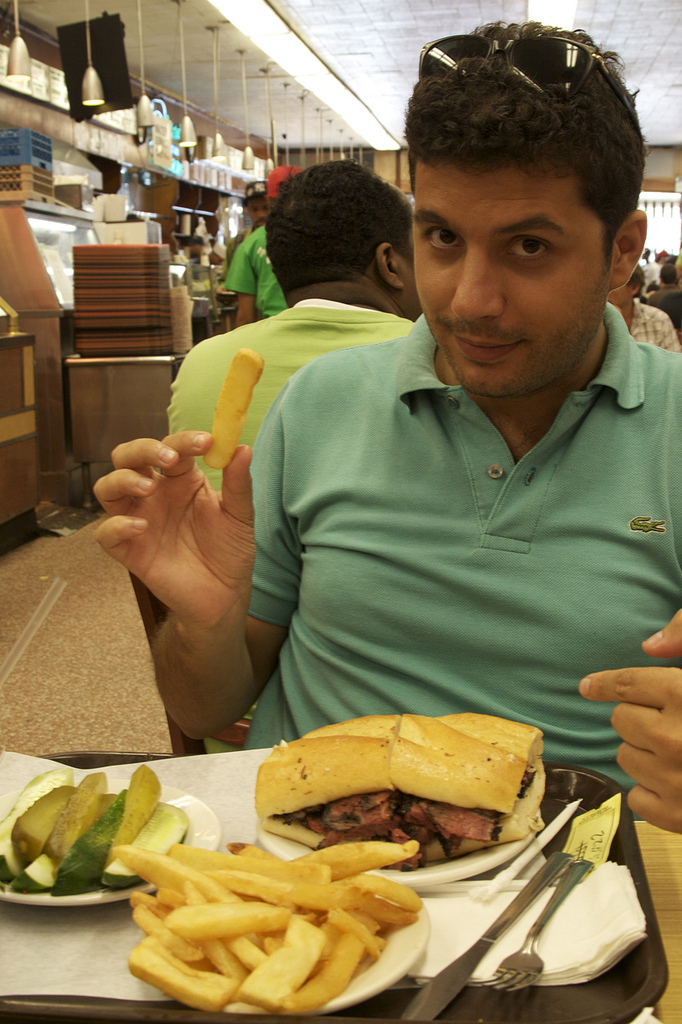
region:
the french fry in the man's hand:
[205, 345, 265, 481]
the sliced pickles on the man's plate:
[6, 763, 179, 892]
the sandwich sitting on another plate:
[257, 716, 540, 862]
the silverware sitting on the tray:
[403, 842, 589, 1023]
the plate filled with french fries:
[106, 833, 432, 1010]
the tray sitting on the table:
[8, 751, 657, 1022]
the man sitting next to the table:
[95, 21, 674, 779]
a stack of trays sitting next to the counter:
[66, 241, 171, 357]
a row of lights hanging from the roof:
[1, 2, 316, 181]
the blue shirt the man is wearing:
[232, 302, 681, 753]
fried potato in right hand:
[85, 338, 269, 632]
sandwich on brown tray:
[249, 703, 644, 897]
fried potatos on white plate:
[111, 817, 432, 1010]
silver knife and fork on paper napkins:
[399, 845, 592, 1017]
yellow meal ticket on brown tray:
[553, 779, 632, 889]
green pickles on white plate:
[5, 761, 221, 910]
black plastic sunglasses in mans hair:
[401, 12, 649, 414]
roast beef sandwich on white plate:
[239, 710, 552, 885]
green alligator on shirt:
[617, 511, 673, 541]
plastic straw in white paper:
[458, 788, 591, 910]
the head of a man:
[391, 81, 613, 398]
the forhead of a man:
[454, 165, 528, 235]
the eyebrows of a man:
[500, 200, 564, 238]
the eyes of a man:
[411, 225, 568, 269]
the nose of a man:
[444, 256, 514, 324]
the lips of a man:
[444, 330, 527, 367]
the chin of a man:
[465, 359, 513, 411]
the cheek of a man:
[518, 287, 566, 333]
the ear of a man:
[594, 217, 662, 298]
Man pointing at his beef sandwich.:
[94, 21, 680, 834]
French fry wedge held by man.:
[205, 348, 264, 469]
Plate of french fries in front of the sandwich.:
[110, 838, 418, 1013]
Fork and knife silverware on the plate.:
[401, 852, 591, 1019]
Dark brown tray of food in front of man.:
[0, 716, 670, 1022]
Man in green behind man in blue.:
[166, 159, 422, 495]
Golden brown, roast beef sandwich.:
[256, 711, 545, 869]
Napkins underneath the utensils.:
[409, 860, 647, 987]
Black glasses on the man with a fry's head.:
[418, 37, 640, 125]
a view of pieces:
[45, 806, 191, 893]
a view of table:
[9, 928, 137, 1005]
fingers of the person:
[598, 608, 661, 817]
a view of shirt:
[308, 465, 639, 826]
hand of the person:
[38, 418, 277, 663]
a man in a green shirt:
[252, 33, 680, 789]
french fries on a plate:
[123, 850, 409, 981]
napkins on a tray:
[373, 884, 656, 959]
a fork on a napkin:
[490, 880, 600, 986]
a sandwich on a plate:
[260, 719, 529, 847]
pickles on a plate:
[6, 780, 191, 875]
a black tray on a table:
[18, 754, 662, 1017]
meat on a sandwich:
[328, 787, 478, 829]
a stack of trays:
[75, 243, 167, 352]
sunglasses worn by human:
[407, 29, 642, 146]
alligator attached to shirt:
[623, 506, 671, 542]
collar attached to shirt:
[395, 301, 650, 432]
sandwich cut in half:
[248, 707, 547, 871]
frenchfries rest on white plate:
[109, 829, 427, 1019]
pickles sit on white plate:
[0, 761, 189, 895]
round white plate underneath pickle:
[0, 770, 223, 916]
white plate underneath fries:
[103, 827, 428, 1021]